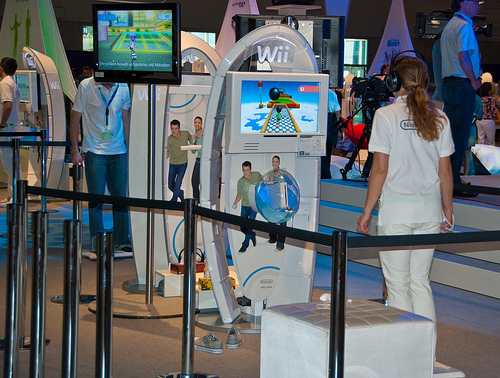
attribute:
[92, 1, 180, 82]
tv — suspended, flat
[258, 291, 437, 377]
cube — white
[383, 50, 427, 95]
headphones — black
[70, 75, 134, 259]
guy — pictured, here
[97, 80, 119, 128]
lanyard — blue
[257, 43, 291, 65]
lettering — white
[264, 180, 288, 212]
console — wii, white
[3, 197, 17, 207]
shoes — tan, grey, white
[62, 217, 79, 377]
metal — silver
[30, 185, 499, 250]
straps — black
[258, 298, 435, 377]
bench — white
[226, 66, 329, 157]
game — wii, white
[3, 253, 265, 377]
carpet — brown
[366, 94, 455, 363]
shirt — white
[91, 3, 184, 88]
television — black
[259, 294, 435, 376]
ottoman — white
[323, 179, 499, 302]
stairs — white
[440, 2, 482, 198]
person — pictured, here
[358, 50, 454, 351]
person — pictured, here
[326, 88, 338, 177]
person — pictured, here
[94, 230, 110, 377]
pole — silver